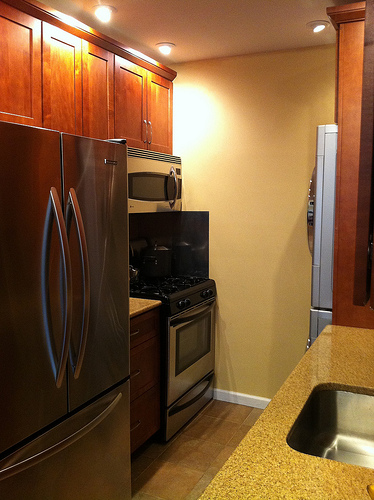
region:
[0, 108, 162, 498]
large stainless steel refrigerator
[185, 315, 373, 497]
small granite sink top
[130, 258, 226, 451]
stainless steel kitchen range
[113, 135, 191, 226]
stainless steel microwave oven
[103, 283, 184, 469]
small granite kitchen drawers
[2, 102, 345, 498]
stainless steel kitchen appliances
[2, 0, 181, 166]
cherry wood kitchen cabinets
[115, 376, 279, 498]
brown granite tile floor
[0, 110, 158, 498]
large double door refrigerator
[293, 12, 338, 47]
small overhead kitchen light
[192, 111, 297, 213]
The paint color is light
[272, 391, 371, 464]
The sink is empty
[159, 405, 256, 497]
The floor is tiled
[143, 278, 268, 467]
The stove is stainless steel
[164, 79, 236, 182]
The light is shining on the wall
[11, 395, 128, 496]
The freezer is a drawer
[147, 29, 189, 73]
The light is still on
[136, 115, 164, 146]
The cupboard has handles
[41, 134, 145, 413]
The fridge is stainless steel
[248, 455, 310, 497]
The counter top is tan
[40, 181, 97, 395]
handles on the refrigerator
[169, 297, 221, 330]
the handle of the oven door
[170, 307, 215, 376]
a window on the oven door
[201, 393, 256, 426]
a gray tile on the floor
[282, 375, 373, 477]
a metal sink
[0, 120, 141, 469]
black refrigerator doors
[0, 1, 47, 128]
brown wooden cabinet doors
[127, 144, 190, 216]
a gray metal microwave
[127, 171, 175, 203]
a microwave window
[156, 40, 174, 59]
a light on the ceiling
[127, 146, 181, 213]
Stainless steel microwave.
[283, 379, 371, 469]
Stainless steel kitchen sink.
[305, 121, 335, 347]
Sideview of Stainless steel refrigerator.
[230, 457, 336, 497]
Mustard colored granite countertop.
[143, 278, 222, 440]
Black and stainless steel gas cook stove.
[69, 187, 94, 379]
Right stainless steel handle to refrigerator.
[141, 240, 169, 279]
Five gallon pot atop stove.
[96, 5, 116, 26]
Recessed lighting over stove.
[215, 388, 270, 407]
White kitchen baseboard.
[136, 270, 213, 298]
Gas cook top kitchen stove.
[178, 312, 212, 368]
Clear glass window on door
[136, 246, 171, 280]
Large black cooking pot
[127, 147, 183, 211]
Stainless steal microwave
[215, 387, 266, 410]
white trim baseboard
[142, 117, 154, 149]
Silver tone handles on cabinets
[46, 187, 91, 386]
Stainless steal handles on fridge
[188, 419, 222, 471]
Light brown hardwood floor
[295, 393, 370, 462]
Deep stainless steal sink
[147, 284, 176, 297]
Black burner on stove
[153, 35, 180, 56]
Light hanging from ceiling